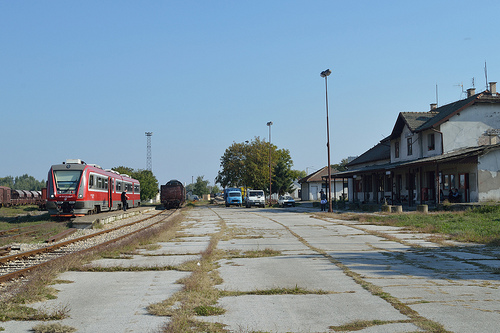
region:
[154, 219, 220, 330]
floor is covered of grasses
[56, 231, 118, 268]
train way is mad of rocks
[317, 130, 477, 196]
building are beside the road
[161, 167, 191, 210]
the train is in motion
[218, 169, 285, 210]
two trucks ar moving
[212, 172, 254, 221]
truck is blue in color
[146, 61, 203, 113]
sky is clear blue in color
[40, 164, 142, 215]
a grey and red light rail train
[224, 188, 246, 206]
a sky blue pickup truck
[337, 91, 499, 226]
a two story building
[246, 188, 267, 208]
a large white vehicle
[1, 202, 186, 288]
a railroad track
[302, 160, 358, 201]
a 1 story house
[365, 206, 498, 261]
a front lawn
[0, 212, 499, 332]
apaved road with weeds growing on it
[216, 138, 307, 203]
a group of trees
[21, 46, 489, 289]
a train passing through a residential area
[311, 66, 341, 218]
a street light in the area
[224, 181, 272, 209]
blue and white trucks on the street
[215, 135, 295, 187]
a big tree in the neighborhood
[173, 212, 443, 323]
a rugged street in a neighborhood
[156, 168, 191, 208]
another train car in the area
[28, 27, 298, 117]
clear sky above the area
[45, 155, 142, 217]
red and grey train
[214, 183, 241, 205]
blue truck parked on the road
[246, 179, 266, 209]
white truck parked on the road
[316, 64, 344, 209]
tall wooden light pole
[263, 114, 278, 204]
tall wooden light pole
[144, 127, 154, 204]
metal electric grid pole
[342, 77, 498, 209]
white worn down house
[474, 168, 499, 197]
missing patch of pain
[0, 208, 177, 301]
metal and wood train track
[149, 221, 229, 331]
patch of brown grass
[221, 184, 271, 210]
Two vehicles parked side by side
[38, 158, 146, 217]
A red and silver train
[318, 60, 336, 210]
A tall light pole with a man next to it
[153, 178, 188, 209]
A ruusty brown train car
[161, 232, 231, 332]
A concrete area with grass sticking out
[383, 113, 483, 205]
A gray and brown building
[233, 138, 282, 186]
A leafy green tree top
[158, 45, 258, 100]
A gray cloudless sky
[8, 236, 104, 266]
A portion of train track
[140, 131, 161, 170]
A power line pole